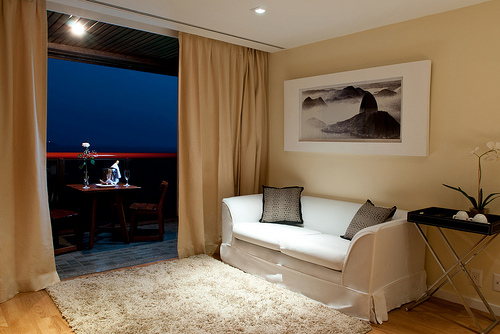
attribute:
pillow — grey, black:
[342, 197, 398, 245]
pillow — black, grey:
[259, 182, 305, 225]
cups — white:
[446, 201, 491, 231]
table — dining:
[68, 177, 140, 253]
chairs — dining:
[141, 165, 171, 247]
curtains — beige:
[170, 28, 287, 264]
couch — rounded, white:
[216, 185, 430, 327]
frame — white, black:
[277, 53, 439, 160]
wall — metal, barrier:
[266, 97, 358, 148]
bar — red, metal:
[43, 136, 218, 164]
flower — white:
[440, 143, 498, 210]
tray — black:
[408, 200, 493, 241]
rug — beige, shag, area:
[45, 253, 371, 332]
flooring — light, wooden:
[383, 302, 496, 332]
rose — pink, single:
[81, 139, 93, 151]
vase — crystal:
[80, 163, 92, 190]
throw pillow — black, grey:
[260, 183, 305, 225]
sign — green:
[38, 104, 163, 191]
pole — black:
[44, 105, 171, 265]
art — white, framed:
[242, 69, 464, 170]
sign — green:
[276, 43, 497, 171]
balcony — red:
[47, 150, 182, 200]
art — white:
[292, 76, 405, 144]